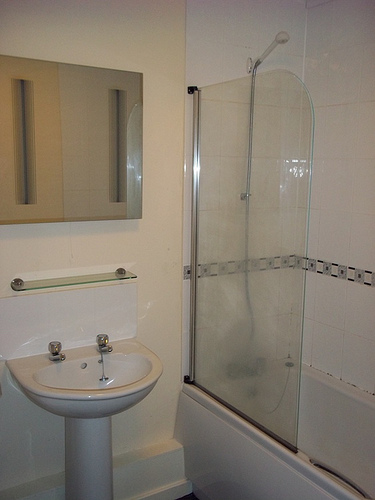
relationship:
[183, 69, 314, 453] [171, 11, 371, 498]
wall separating shower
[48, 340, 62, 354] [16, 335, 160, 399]
knob attached to sink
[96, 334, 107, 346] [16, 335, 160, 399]
knob attached to sink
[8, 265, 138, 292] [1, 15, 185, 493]
shelf attached to wall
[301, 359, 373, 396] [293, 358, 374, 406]
mold growing on base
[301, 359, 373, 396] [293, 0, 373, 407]
mold growing on wall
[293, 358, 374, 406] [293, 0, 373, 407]
base belonging to wall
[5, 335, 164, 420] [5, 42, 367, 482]
sink standing inside bathroom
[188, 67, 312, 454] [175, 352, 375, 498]
door leading to bathtub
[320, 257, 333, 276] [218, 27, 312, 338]
tile lining shower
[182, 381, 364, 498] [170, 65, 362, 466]
track guiding door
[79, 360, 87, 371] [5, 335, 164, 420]
hole belonging to sink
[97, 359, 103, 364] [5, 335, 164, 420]
hole belonging to sink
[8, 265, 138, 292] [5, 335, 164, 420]
shelf hanging above sink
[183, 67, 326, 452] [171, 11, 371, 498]
glass separating shower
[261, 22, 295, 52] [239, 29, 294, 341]
head belonging to shower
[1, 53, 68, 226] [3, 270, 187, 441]
door hanging above sink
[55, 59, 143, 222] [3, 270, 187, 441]
door hanging above sink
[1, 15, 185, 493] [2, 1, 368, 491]
wall supporting bathroom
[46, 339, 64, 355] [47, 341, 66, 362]
knob activating faucet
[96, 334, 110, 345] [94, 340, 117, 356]
knob activating faucet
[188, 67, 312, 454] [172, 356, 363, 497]
door built on top of bathtub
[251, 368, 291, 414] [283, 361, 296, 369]
chain holding plug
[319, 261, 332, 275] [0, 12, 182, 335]
design built into wall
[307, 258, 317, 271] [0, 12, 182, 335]
design built into wall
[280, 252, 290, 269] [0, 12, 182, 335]
design built into wall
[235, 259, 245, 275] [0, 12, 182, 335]
design built into wall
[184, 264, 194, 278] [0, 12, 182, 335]
design built into wall